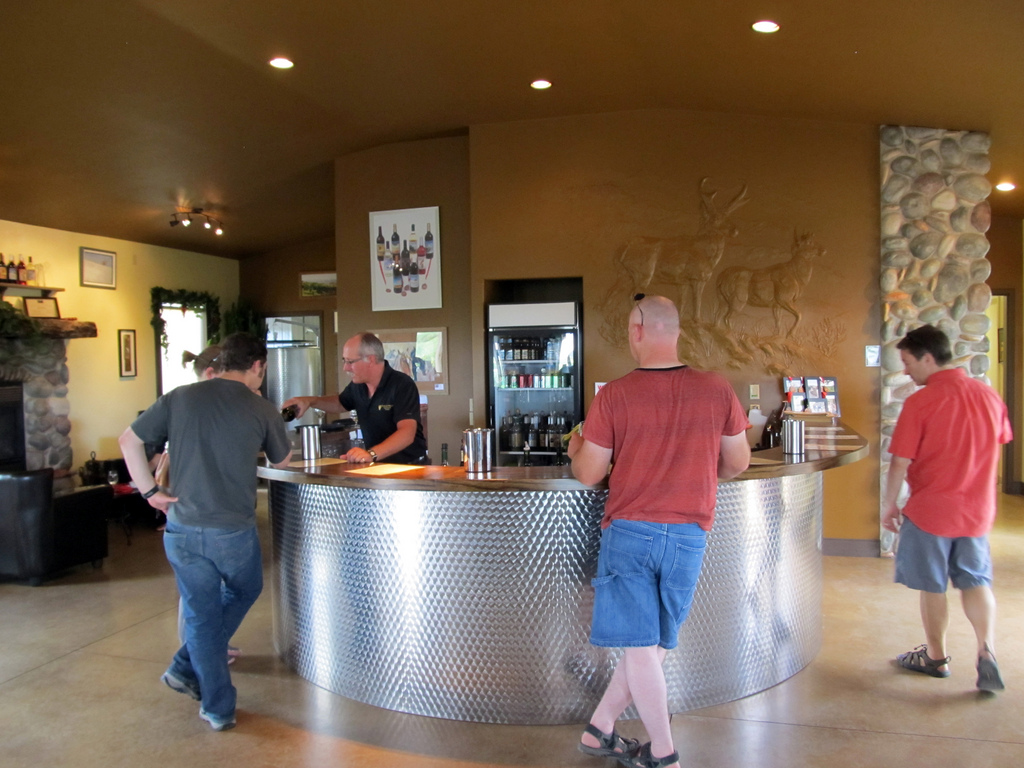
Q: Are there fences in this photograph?
A: No, there are no fences.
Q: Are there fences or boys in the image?
A: No, there are no fences or boys.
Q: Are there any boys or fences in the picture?
A: No, there are no fences or boys.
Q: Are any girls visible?
A: No, there are no girls.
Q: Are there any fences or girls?
A: No, there are no girls or fences.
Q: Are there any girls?
A: No, there are no girls.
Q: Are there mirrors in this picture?
A: No, there are no mirrors.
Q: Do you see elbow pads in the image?
A: No, there are no elbow pads.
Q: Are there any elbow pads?
A: No, there are no elbow pads.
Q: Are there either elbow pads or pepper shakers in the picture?
A: No, there are no elbow pads or pepper shakers.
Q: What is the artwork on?
A: The artwork is on the wall.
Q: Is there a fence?
A: No, there are no fences.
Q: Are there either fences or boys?
A: No, there are no fences or boys.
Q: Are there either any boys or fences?
A: No, there are no fences or boys.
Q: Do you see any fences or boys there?
A: No, there are no fences or boys.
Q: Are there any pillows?
A: No, there are no pillows.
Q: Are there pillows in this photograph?
A: No, there are no pillows.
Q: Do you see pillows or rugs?
A: No, there are no pillows or rugs.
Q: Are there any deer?
A: Yes, there is a deer.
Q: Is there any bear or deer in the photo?
A: Yes, there is a deer.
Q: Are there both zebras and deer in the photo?
A: No, there is a deer but no zebras.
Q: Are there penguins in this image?
A: No, there are no penguins.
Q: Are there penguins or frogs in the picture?
A: No, there are no penguins or frogs.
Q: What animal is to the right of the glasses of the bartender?
A: The animal is a deer.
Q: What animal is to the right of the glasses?
A: The animal is a deer.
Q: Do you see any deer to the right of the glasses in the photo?
A: Yes, there is a deer to the right of the glasses.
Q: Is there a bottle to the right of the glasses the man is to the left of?
A: No, there is a deer to the right of the glasses.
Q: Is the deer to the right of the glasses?
A: Yes, the deer is to the right of the glasses.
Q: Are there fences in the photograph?
A: No, there are no fences.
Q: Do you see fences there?
A: No, there are no fences.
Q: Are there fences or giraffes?
A: No, there are no fences or giraffes.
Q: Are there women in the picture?
A: No, there are no women.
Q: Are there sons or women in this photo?
A: No, there are no women or sons.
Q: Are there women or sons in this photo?
A: No, there are no women or sons.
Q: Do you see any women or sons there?
A: No, there are no women or sons.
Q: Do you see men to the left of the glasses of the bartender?
A: Yes, there is a man to the left of the glasses.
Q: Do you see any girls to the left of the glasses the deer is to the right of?
A: No, there is a man to the left of the glasses.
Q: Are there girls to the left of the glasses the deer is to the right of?
A: No, there is a man to the left of the glasses.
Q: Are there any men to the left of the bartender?
A: Yes, there is a man to the left of the bartender.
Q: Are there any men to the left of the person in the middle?
A: Yes, there is a man to the left of the bartender.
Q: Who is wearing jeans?
A: The man is wearing jeans.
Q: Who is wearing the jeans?
A: The man is wearing jeans.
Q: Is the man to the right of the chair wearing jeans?
A: Yes, the man is wearing jeans.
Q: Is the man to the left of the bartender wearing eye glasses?
A: No, the man is wearing jeans.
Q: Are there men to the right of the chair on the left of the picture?
A: Yes, there is a man to the right of the chair.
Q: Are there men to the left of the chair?
A: No, the man is to the right of the chair.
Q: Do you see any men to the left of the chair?
A: No, the man is to the right of the chair.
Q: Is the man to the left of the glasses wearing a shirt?
A: Yes, the man is wearing a shirt.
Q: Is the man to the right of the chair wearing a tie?
A: No, the man is wearing a shirt.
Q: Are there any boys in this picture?
A: No, there are no boys.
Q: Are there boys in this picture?
A: No, there are no boys.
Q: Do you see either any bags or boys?
A: No, there are no boys or bags.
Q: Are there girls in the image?
A: No, there are no girls.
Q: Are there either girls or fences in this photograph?
A: No, there are no girls or fences.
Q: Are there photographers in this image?
A: No, there are no photographers.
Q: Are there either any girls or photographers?
A: No, there are no photographers or girls.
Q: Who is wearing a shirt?
A: The bartender is wearing a shirt.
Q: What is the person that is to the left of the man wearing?
A: The bartender is wearing a shirt.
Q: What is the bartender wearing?
A: The bartender is wearing a shirt.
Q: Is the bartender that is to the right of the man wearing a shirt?
A: Yes, the bartender is wearing a shirt.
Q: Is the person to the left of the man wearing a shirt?
A: Yes, the bartender is wearing a shirt.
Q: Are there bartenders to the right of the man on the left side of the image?
A: Yes, there is a bartender to the right of the man.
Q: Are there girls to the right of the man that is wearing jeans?
A: No, there is a bartender to the right of the man.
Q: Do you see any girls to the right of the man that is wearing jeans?
A: No, there is a bartender to the right of the man.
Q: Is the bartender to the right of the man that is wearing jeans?
A: Yes, the bartender is to the right of the man.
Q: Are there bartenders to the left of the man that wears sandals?
A: Yes, there is a bartender to the left of the man.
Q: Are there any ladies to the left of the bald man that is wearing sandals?
A: No, there is a bartender to the left of the man.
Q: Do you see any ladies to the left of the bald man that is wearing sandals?
A: No, there is a bartender to the left of the man.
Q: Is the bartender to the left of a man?
A: Yes, the bartender is to the left of a man.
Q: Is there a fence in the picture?
A: No, there are no fences.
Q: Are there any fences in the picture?
A: No, there are no fences.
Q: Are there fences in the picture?
A: No, there are no fences.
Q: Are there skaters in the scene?
A: No, there are no skaters.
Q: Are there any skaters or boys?
A: No, there are no skaters or boys.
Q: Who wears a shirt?
A: The man wears a shirt.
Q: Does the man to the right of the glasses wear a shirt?
A: Yes, the man wears a shirt.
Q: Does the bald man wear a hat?
A: No, the man wears a shirt.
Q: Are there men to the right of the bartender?
A: Yes, there is a man to the right of the bartender.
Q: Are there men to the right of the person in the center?
A: Yes, there is a man to the right of the bartender.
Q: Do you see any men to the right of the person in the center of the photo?
A: Yes, there is a man to the right of the bartender.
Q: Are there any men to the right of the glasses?
A: Yes, there is a man to the right of the glasses.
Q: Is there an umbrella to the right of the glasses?
A: No, there is a man to the right of the glasses.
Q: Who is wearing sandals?
A: The man is wearing sandals.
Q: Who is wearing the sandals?
A: The man is wearing sandals.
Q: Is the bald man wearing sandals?
A: Yes, the man is wearing sandals.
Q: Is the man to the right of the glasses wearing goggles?
A: No, the man is wearing sandals.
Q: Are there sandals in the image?
A: Yes, there are sandals.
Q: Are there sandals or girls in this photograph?
A: Yes, there are sandals.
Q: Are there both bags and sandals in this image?
A: No, there are sandals but no bags.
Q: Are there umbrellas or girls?
A: No, there are no girls or umbrellas.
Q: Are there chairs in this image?
A: Yes, there is a chair.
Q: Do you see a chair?
A: Yes, there is a chair.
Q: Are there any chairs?
A: Yes, there is a chair.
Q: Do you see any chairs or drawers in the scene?
A: Yes, there is a chair.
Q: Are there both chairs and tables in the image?
A: No, there is a chair but no tables.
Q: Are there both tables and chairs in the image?
A: No, there is a chair but no tables.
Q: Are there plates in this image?
A: No, there are no plates.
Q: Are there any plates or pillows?
A: No, there are no plates or pillows.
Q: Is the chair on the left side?
A: Yes, the chair is on the left of the image.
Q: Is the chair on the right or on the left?
A: The chair is on the left of the image.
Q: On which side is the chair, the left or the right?
A: The chair is on the left of the image.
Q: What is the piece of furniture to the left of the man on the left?
A: The piece of furniture is a chair.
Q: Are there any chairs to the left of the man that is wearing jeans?
A: Yes, there is a chair to the left of the man.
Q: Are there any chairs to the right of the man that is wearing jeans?
A: No, the chair is to the left of the man.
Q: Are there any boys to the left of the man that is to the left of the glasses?
A: No, there is a chair to the left of the man.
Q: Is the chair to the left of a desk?
A: No, the chair is to the left of a man.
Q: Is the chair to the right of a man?
A: No, the chair is to the left of a man.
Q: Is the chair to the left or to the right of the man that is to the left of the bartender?
A: The chair is to the left of the man.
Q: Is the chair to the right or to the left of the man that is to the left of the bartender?
A: The chair is to the left of the man.